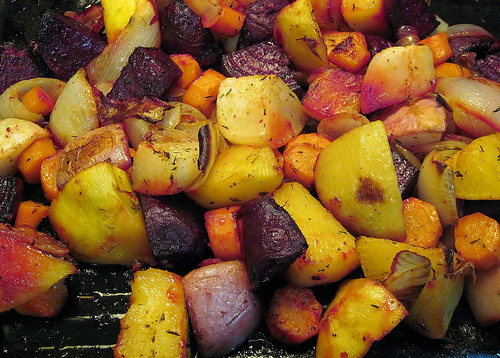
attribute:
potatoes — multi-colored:
[83, 77, 336, 163]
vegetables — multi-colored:
[119, 77, 327, 288]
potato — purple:
[230, 196, 308, 286]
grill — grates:
[69, 284, 119, 354]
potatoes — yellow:
[282, 122, 385, 269]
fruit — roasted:
[18, 27, 407, 327]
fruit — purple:
[227, 189, 300, 286]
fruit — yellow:
[355, 43, 445, 108]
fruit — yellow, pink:
[1, 232, 86, 323]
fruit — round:
[445, 205, 495, 256]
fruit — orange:
[178, 62, 226, 112]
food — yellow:
[129, 268, 182, 355]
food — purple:
[238, 197, 298, 267]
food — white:
[213, 73, 303, 149]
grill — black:
[31, 260, 110, 354]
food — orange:
[322, 310, 381, 318]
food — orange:
[291, 194, 403, 277]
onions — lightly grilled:
[2, 2, 167, 138]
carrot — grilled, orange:
[167, 50, 197, 99]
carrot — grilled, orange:
[181, 64, 224, 114]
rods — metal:
[16, 285, 135, 355]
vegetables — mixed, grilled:
[5, 69, 159, 319]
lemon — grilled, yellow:
[306, 119, 419, 252]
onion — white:
[79, 9, 169, 90]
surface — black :
[69, 323, 103, 345]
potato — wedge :
[280, 155, 406, 258]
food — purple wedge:
[232, 201, 310, 285]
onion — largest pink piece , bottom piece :
[189, 267, 277, 356]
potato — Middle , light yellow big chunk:
[196, 72, 317, 138]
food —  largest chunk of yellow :
[208, 72, 344, 157]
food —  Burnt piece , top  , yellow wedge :
[64, 56, 431, 315]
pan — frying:
[65, 275, 111, 353]